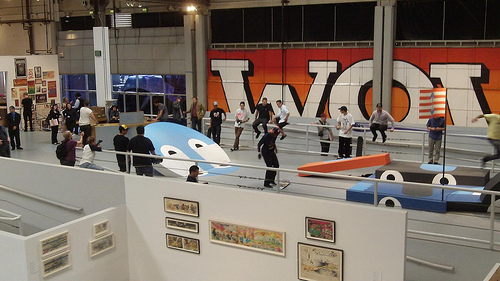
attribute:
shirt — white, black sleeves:
[81, 140, 99, 164]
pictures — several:
[13, 57, 31, 79]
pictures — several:
[35, 72, 46, 87]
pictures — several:
[16, 82, 33, 93]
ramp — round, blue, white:
[144, 120, 233, 174]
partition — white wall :
[21, 196, 135, 275]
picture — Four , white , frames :
[92, 220, 109, 236]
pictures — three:
[160, 192, 202, 254]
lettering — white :
[208, 55, 494, 127]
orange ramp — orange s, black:
[294, 151, 391, 170]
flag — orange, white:
[416, 85, 449, 122]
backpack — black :
[55, 140, 68, 160]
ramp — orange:
[98, 101, 235, 195]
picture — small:
[13, 57, 28, 81]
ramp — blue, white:
[146, 121, 237, 180]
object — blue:
[132, 120, 237, 182]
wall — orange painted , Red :
[206, 51, 488, 123]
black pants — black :
[259, 151, 285, 191]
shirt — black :
[48, 96, 86, 133]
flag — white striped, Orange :
[394, 84, 471, 141]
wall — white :
[3, 43, 66, 139]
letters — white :
[212, 53, 482, 125]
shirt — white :
[335, 115, 356, 140]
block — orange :
[295, 145, 393, 177]